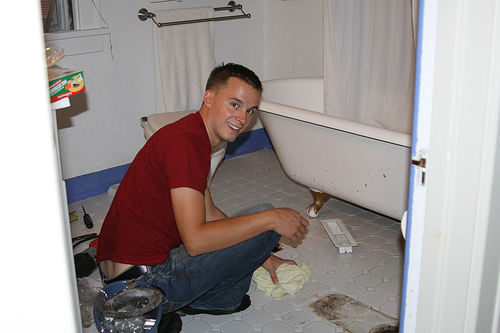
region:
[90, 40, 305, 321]
young man in red shirt and blue jeans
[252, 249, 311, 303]
hand holding and yellow towel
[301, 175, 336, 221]
brass metal foot of a bath tub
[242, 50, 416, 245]
white standing bath tub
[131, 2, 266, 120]
towel rod with white towel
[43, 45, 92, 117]
green and red box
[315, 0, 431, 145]
white shower curtain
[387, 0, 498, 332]
white door with blue edge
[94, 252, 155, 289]
black leather belt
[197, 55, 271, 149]
face of a man with short brown hair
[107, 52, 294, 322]
man fixing bathroom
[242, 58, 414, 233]
white claw foot bathtub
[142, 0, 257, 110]
white towel hung on wall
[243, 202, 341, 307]
man wiping down bathroom floor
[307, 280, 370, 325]
dirt on white tile bathroom floor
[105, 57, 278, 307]
man looking at the camera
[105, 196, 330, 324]
man wearing blue jeans with a black belt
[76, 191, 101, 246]
screwdriver on bathroom floor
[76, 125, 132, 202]
white walls with baseboard painted purple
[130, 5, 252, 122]
a white towel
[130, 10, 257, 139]
a white towel hanging on the wall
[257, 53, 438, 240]
a white bath tub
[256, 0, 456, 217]
a white shower curtain on the bath tub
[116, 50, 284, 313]
a male wearing jeans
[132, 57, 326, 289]
a male wearing a red shirt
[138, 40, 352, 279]
a male with brown hair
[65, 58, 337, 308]
a male wearing a black belt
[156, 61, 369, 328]
a male holding a towel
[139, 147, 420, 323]
white tile floor in the bathroom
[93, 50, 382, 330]
man working in bathroom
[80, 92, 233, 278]
man wearing red shirt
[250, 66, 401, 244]
white claw footed bathtub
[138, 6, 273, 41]
towel rack on wall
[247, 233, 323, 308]
man holding cleaning rag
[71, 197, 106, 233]
screw driver laying on floor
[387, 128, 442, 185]
door jam to bathroom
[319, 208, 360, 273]
air vent removed from floor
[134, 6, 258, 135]
white towel on towel rack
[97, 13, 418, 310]
man squatting in a bathroom.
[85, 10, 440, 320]
man working in a bathroom.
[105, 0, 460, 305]
person squatting in a bathroom.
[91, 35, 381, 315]
person working in a bathroom.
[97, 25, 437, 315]
young man working on a bathroom floor.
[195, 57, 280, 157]
person with dark colored hair.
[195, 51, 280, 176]
male with dark colored hair.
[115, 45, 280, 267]
young man wearing a red shirt.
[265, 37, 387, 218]
part of a white bath tub.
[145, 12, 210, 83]
a white bath towel.